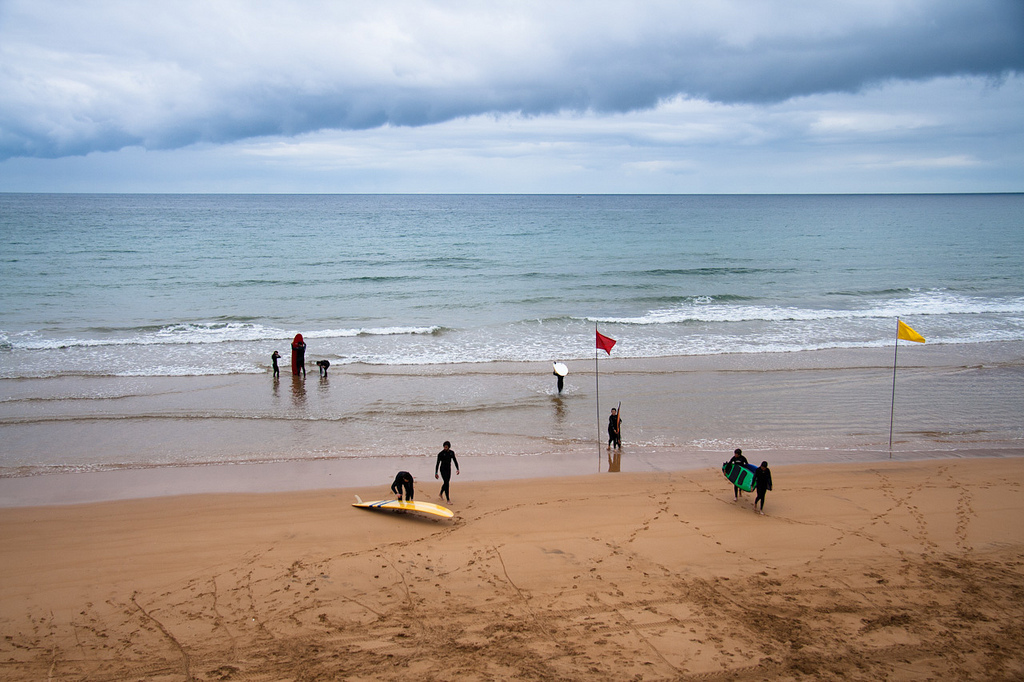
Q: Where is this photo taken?
A: By the beach.